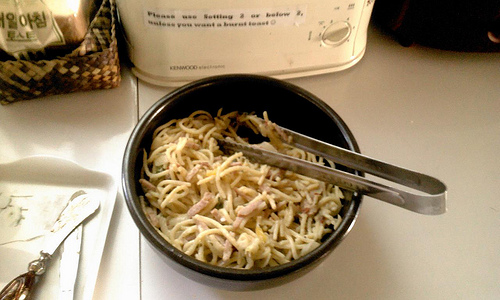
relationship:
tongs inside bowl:
[216, 106, 450, 219] [121, 70, 369, 282]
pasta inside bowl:
[139, 106, 347, 270] [121, 70, 369, 282]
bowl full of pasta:
[121, 70, 369, 282] [139, 106, 347, 270]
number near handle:
[330, 18, 335, 26] [323, 21, 351, 46]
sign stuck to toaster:
[142, 1, 308, 32] [113, 0, 381, 94]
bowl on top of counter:
[121, 70, 369, 282] [0, 48, 497, 299]